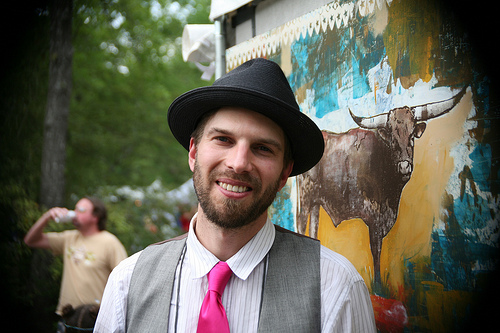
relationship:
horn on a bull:
[342, 104, 387, 135] [295, 83, 473, 285]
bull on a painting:
[295, 83, 473, 285] [270, 0, 497, 330]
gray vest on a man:
[128, 222, 329, 333] [93, 55, 375, 333]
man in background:
[93, 55, 375, 333] [1, 0, 215, 332]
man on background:
[93, 55, 375, 333] [2, 1, 498, 119]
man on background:
[93, 55, 375, 333] [53, 23, 146, 130]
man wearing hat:
[93, 55, 375, 333] [168, 55, 327, 177]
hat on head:
[158, 57, 331, 179] [178, 98, 301, 228]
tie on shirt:
[195, 260, 232, 331] [90, 213, 384, 331]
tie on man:
[195, 260, 232, 331] [64, 67, 376, 330]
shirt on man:
[90, 213, 384, 331] [64, 67, 376, 330]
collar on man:
[181, 212, 278, 274] [93, 55, 375, 333]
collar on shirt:
[181, 212, 278, 274] [95, 202, 379, 331]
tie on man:
[195, 260, 232, 331] [93, 55, 375, 333]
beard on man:
[190, 155, 284, 235] [93, 55, 375, 333]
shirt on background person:
[46, 230, 128, 309] [23, 195, 128, 330]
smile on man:
[203, 172, 266, 207] [93, 55, 375, 333]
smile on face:
[203, 172, 266, 207] [176, 101, 289, 231]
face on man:
[176, 101, 289, 231] [93, 55, 375, 333]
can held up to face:
[51, 211, 76, 227] [194, 107, 286, 224]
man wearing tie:
[117, 41, 375, 318] [194, 256, 240, 327]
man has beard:
[93, 55, 375, 333] [190, 142, 284, 228]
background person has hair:
[23, 195, 128, 330] [87, 195, 109, 233]